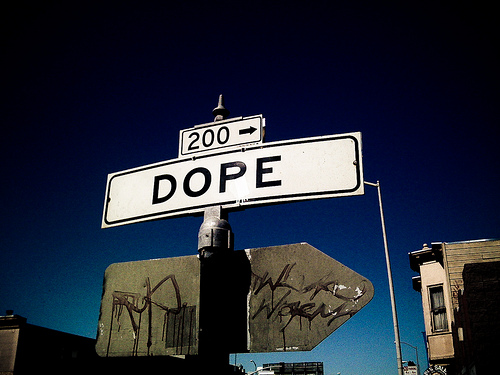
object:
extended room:
[416, 249, 456, 361]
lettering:
[188, 132, 200, 150]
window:
[427, 286, 451, 331]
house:
[408, 237, 500, 374]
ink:
[291, 306, 315, 322]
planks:
[442, 239, 500, 353]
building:
[407, 237, 499, 374]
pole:
[195, 91, 230, 373]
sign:
[90, 241, 375, 358]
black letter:
[151, 174, 176, 204]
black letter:
[182, 167, 211, 198]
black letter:
[218, 161, 246, 193]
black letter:
[256, 155, 283, 188]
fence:
[419, 246, 498, 373]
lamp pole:
[377, 185, 409, 373]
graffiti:
[251, 259, 344, 329]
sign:
[102, 131, 363, 230]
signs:
[177, 114, 264, 158]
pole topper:
[195, 196, 241, 259]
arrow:
[238, 126, 257, 136]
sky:
[5, 0, 496, 374]